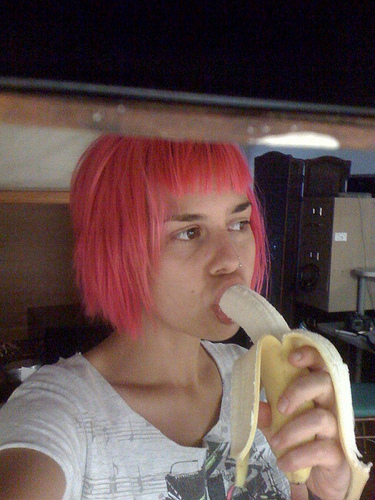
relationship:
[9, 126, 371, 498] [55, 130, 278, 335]
person has hair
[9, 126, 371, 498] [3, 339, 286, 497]
person wears shirt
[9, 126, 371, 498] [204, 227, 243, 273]
person has nose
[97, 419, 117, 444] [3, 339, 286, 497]
music note on shirt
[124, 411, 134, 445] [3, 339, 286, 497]
music note on shirt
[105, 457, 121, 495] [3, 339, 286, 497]
music note on shirt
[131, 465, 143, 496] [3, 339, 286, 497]
music note on shirt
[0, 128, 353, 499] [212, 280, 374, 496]
person sucking on banana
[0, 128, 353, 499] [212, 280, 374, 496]
person eating banana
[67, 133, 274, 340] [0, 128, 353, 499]
hair on person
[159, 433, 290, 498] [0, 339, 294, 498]
design on shirt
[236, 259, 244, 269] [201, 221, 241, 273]
stud in nose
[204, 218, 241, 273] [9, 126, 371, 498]
nose on person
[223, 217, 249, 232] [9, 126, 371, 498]
eye on person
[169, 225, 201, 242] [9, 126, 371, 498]
eye on person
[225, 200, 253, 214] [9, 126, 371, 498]
eyebrow on person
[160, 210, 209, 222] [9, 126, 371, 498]
eyebrow on person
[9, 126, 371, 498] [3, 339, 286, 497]
person wearing shirt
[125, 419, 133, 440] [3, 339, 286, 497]
music note on shirt